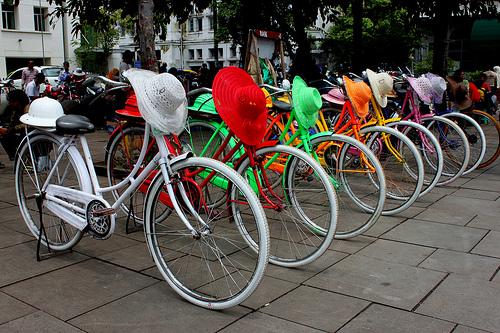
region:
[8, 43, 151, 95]
people behind the bikes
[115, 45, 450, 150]
colorful hats on bikes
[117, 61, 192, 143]
a hat color white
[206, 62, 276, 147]
a hat color red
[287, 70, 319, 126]
a hat color green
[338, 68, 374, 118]
a hat color orange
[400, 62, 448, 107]
two hats color purple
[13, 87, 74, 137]
a white hat on back bike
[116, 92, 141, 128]
a red hat on back bike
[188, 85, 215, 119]
a green hat on back bike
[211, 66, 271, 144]
A round red hat.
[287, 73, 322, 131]
A green round hat.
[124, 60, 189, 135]
A white hat.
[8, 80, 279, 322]
A white framed bicycle.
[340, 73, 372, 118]
A round orange hat.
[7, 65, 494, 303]
A row of colorful bicycles.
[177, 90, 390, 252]
A lime green bicycle.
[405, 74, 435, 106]
A round light pink hat.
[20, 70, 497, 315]
A row of bicycles with hats on them.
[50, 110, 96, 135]
A black bicycle seat.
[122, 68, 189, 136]
white hat on white bicycle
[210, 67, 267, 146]
red hat on red bicycle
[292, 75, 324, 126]
green hat on green bicycle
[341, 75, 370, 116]
orange hat on red bicycle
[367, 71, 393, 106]
tan hat on orange bicycle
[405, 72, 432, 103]
purple hat on purple bicycle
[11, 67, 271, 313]
white bicycle with two hats on it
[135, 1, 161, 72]
tree trunk behind bicycles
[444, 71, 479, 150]
man wearing black backpack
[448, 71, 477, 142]
man wearing brown shirt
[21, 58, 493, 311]
a line of bikes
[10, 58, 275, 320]
white bike with whites hats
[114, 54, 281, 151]
red bike with red hats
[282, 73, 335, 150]
green bike with green hat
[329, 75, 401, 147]
orange bikes with orange hats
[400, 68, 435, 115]
a pink hat on a bike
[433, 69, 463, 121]
a purple hat on a bike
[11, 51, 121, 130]
people behind colored bikes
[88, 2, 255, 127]
a green tree behind the bikes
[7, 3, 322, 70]
the buildings are white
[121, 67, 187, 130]
white straw hat on a white bike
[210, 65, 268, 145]
a red hat on a red bike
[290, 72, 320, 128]
a green hat on a green bike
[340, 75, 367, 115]
an orange hat on an orange bike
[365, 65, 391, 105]
a yellow hat on a yellow bike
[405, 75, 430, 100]
a pink hat on a pink bike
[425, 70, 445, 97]
a purple hat on a purple bike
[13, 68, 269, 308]
a white bicycle on the sidewalk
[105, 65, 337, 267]
a red bicycle on the sidewalk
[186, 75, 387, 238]
a green bicycle on the sidewalk